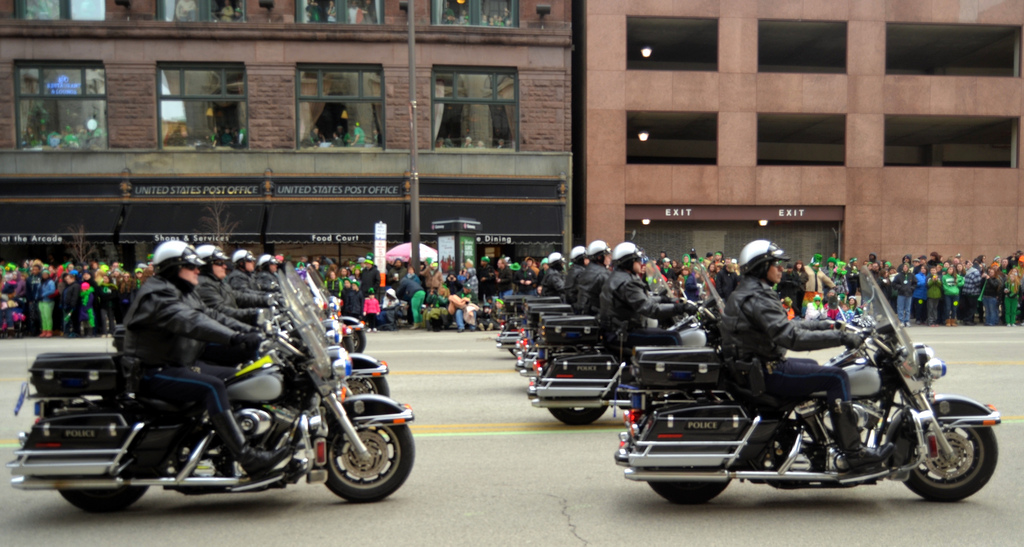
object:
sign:
[121, 178, 261, 200]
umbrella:
[383, 240, 440, 263]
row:
[9, 238, 411, 510]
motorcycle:
[14, 272, 423, 516]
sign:
[125, 178, 405, 199]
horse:
[2, 238, 419, 514]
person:
[711, 235, 899, 467]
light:
[634, 126, 657, 143]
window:
[430, 64, 518, 148]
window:
[296, 60, 384, 150]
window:
[154, 63, 245, 146]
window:
[17, 63, 104, 149]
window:
[433, 0, 520, 29]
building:
[0, 0, 573, 315]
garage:
[589, 0, 1022, 279]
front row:
[492, 235, 1001, 514]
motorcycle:
[610, 267, 1002, 508]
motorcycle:
[531, 253, 753, 426]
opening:
[621, 13, 722, 74]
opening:
[618, 105, 724, 167]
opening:
[755, 108, 849, 166]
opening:
[756, 18, 849, 75]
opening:
[877, 20, 1023, 78]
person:
[113, 234, 306, 477]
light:
[640, 45, 653, 57]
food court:
[3, 172, 569, 293]